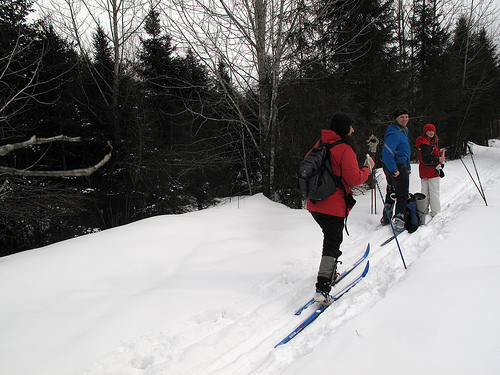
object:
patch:
[359, 330, 426, 371]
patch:
[186, 292, 246, 337]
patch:
[389, 265, 420, 325]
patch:
[93, 319, 141, 347]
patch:
[50, 261, 90, 301]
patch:
[211, 278, 244, 318]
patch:
[77, 302, 193, 351]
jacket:
[304, 129, 372, 218]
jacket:
[382, 123, 412, 174]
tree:
[467, 0, 498, 145]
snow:
[1, 140, 500, 375]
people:
[415, 123, 445, 218]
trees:
[1, 1, 498, 259]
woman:
[297, 112, 375, 306]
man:
[380, 107, 412, 233]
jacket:
[415, 135, 441, 179]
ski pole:
[372, 169, 407, 269]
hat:
[393, 105, 411, 127]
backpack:
[297, 136, 341, 202]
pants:
[307, 210, 344, 292]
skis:
[274, 260, 370, 348]